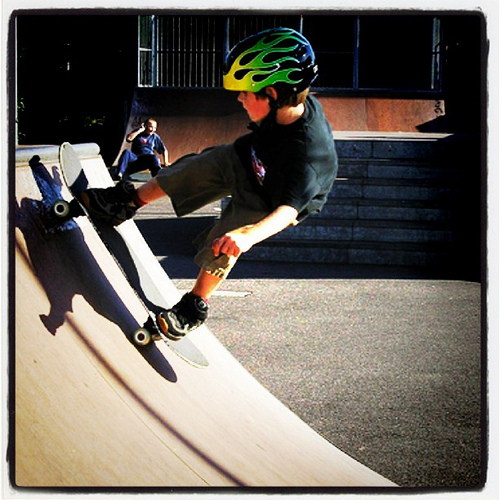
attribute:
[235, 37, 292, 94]
flame — yellow, green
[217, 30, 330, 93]
helmet — black, green, yellow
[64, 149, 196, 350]
skateboard — black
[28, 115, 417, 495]
ramp — wooden, brown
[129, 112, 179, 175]
skater — sitting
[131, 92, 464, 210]
ramp — in background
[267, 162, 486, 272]
steps — grey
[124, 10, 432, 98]
fence — atop ramp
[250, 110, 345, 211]
shirt — black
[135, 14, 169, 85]
post — white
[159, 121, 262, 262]
shorts — colored, tan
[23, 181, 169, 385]
shadow — black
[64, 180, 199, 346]
shoes — black